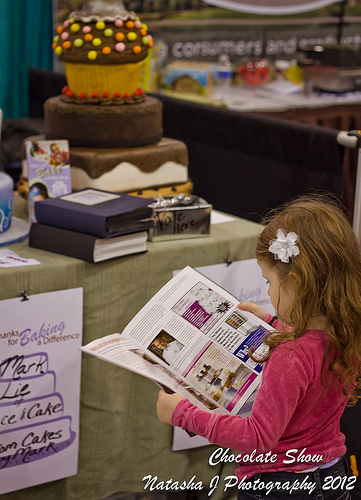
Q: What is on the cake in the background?
A: Giant cupcake.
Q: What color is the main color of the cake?
A: Brown.